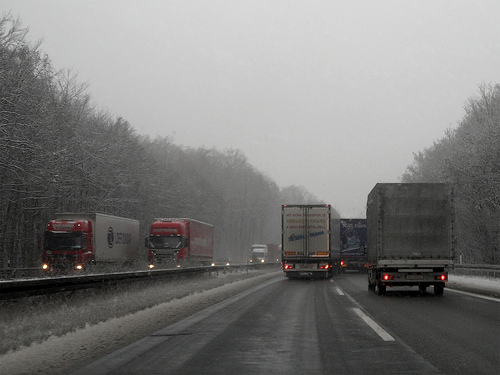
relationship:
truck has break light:
[275, 198, 336, 285] [279, 262, 333, 276]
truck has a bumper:
[365, 179, 459, 286] [379, 257, 462, 284]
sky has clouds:
[243, 72, 349, 156] [284, 71, 299, 80]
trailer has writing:
[85, 208, 145, 269] [104, 226, 134, 251]